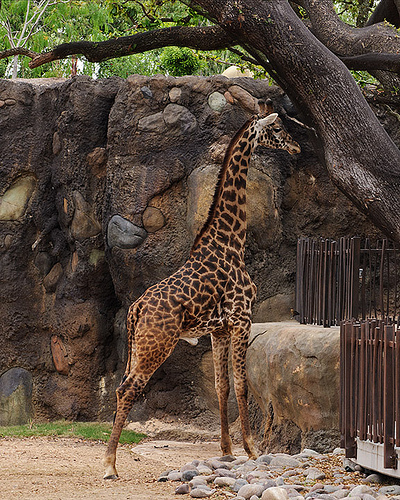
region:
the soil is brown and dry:
[66, 463, 76, 488]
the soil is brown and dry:
[73, 460, 84, 480]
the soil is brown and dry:
[84, 468, 93, 486]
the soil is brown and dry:
[75, 461, 96, 487]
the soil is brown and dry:
[62, 483, 80, 496]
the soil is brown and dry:
[81, 473, 99, 493]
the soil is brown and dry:
[79, 472, 85, 484]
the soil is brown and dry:
[85, 479, 94, 491]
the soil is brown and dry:
[82, 480, 88, 488]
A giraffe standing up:
[101, 111, 302, 479]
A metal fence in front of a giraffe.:
[293, 234, 398, 327]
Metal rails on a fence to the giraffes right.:
[338, 318, 398, 467]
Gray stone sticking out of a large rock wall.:
[106, 213, 147, 252]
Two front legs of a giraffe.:
[209, 315, 259, 461]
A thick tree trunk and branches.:
[1, 1, 398, 246]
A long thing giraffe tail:
[118, 309, 132, 385]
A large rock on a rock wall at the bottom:
[1, 366, 34, 427]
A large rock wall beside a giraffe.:
[1, 74, 202, 420]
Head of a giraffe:
[248, 113, 301, 156]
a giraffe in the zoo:
[96, 93, 273, 471]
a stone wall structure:
[10, 81, 177, 270]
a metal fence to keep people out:
[319, 304, 399, 470]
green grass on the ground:
[4, 410, 134, 451]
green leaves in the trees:
[0, 4, 234, 82]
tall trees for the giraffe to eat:
[162, 4, 398, 228]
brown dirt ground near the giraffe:
[15, 446, 160, 499]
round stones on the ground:
[225, 459, 370, 499]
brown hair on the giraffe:
[209, 122, 238, 210]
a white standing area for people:
[337, 425, 399, 473]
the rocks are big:
[219, 463, 229, 480]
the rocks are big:
[230, 471, 243, 492]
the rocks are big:
[252, 449, 276, 496]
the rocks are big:
[275, 489, 281, 497]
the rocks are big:
[262, 479, 278, 497]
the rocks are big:
[258, 491, 266, 497]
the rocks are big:
[267, 477, 286, 496]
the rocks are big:
[264, 488, 284, 497]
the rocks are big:
[269, 485, 275, 498]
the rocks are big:
[257, 489, 269, 498]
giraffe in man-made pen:
[77, 100, 383, 478]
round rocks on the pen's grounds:
[157, 460, 329, 496]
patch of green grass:
[32, 420, 104, 440]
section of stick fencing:
[289, 232, 393, 321]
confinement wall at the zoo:
[0, 68, 100, 380]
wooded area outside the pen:
[0, 0, 160, 28]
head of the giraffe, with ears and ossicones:
[236, 88, 304, 160]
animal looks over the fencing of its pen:
[208, 88, 392, 408]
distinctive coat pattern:
[172, 268, 244, 324]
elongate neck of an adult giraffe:
[205, 145, 253, 257]